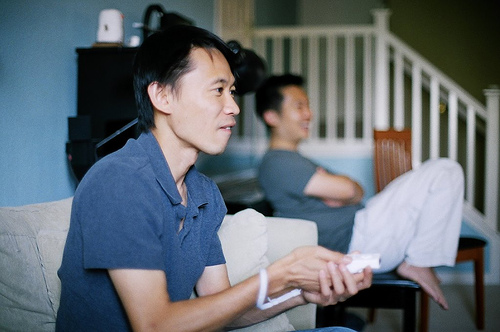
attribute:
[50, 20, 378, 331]
man — playing, sitting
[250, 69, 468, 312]
man — laughing, bare foot, sitting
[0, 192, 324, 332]
couch — tan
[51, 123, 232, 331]
shirt — blue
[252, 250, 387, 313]
controller — white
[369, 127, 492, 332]
chair — wooden, brown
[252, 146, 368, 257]
shirt — grey, polo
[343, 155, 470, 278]
pants — white